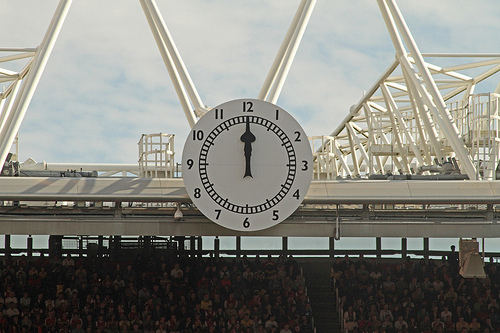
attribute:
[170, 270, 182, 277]
shirt — white 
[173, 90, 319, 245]
clock — white , black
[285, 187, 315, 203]
number — black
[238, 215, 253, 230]
number — black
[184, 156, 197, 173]
number 9 — black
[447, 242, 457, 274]
person — standing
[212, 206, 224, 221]
number — black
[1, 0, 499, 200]
metal structure — white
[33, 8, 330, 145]
sky — cloudy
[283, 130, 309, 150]
number — black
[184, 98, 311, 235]
clock — white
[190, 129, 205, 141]
number — black